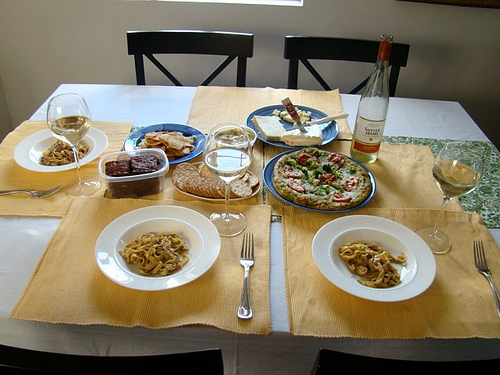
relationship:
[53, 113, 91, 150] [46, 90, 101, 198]
wine in glass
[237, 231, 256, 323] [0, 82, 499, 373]
fork on table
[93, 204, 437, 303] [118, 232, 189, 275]
bowls sitting on food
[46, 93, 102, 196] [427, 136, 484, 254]
wine glass in glass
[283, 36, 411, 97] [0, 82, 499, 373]
chair pushed up to table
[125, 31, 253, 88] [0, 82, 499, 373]
chair pushed up to table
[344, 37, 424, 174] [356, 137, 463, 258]
wine on table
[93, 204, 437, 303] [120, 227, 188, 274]
bowls of food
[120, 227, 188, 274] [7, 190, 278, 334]
food on placemat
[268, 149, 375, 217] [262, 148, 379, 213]
pizza on blue plate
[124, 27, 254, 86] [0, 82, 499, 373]
chair at table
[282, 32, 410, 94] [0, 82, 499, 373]
chair at table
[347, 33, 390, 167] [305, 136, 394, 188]
bottle of wine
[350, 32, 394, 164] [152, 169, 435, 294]
white wine for everyone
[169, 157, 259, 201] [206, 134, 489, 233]
crackers and cheese behind a glass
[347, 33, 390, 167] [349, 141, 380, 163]
bottle of wine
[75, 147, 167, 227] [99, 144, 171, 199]
rectangular plastic container of brownies